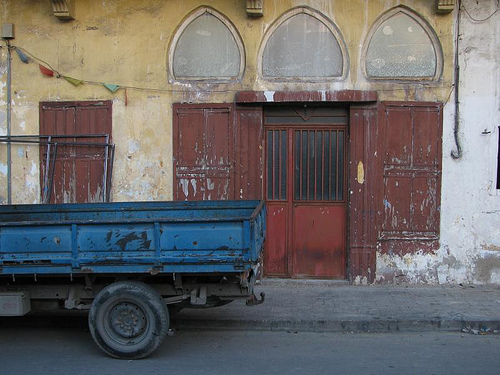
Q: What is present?
A: A car.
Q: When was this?
A: Daytime.